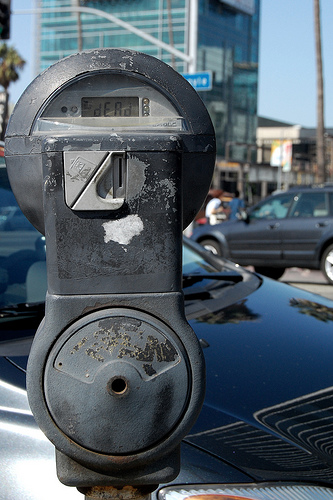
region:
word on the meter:
[83, 91, 138, 126]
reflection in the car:
[277, 284, 325, 324]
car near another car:
[199, 178, 325, 256]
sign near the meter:
[184, 54, 227, 95]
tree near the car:
[0, 35, 32, 84]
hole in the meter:
[98, 361, 142, 404]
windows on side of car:
[245, 182, 332, 225]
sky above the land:
[269, 21, 312, 73]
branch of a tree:
[293, 17, 326, 91]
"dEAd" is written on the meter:
[68, 91, 142, 123]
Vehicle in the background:
[225, 172, 321, 244]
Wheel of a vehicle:
[318, 242, 331, 282]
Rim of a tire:
[326, 252, 331, 274]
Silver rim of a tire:
[326, 252, 331, 276]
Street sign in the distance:
[192, 61, 222, 105]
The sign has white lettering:
[183, 73, 220, 92]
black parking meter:
[3, 44, 221, 498]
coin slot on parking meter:
[112, 152, 127, 194]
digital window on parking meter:
[77, 92, 141, 121]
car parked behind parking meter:
[0, 152, 330, 499]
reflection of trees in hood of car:
[192, 283, 332, 338]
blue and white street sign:
[178, 71, 214, 92]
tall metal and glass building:
[30, 1, 263, 166]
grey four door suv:
[186, 180, 331, 287]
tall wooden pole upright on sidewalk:
[307, 1, 332, 186]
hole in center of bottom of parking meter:
[102, 371, 133, 399]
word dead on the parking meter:
[71, 88, 143, 119]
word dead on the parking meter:
[71, 97, 144, 120]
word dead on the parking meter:
[79, 96, 144, 116]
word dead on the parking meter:
[68, 89, 147, 116]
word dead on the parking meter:
[71, 101, 137, 116]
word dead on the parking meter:
[75, 98, 147, 123]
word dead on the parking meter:
[84, 97, 136, 122]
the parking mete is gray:
[15, 72, 212, 473]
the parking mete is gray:
[25, 48, 206, 466]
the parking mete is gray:
[13, 50, 212, 466]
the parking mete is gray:
[2, 47, 199, 477]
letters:
[93, 98, 136, 117]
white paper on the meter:
[105, 218, 147, 248]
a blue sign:
[187, 71, 215, 87]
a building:
[200, 0, 254, 88]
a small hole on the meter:
[108, 377, 130, 396]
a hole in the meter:
[102, 359, 139, 415]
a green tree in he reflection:
[211, 301, 264, 339]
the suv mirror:
[234, 209, 255, 227]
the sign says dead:
[85, 94, 145, 123]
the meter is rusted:
[88, 483, 144, 497]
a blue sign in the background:
[192, 55, 220, 96]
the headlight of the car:
[197, 488, 243, 499]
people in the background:
[210, 186, 240, 220]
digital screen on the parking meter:
[82, 94, 140, 119]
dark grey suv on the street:
[204, 186, 331, 282]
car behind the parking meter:
[2, 153, 327, 499]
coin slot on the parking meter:
[114, 153, 125, 192]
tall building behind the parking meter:
[23, 4, 266, 191]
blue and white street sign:
[183, 62, 213, 93]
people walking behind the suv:
[204, 187, 244, 223]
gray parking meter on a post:
[11, 44, 217, 498]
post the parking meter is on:
[79, 481, 151, 497]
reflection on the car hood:
[204, 384, 332, 472]